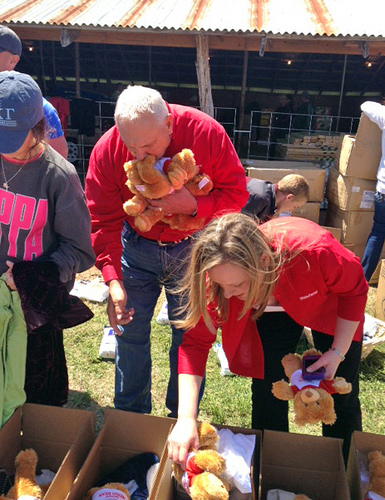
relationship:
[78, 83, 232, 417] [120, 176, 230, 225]
man holding teddy bear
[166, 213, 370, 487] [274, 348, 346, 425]
lady holding teddy bear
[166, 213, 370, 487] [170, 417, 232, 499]
lady holding bear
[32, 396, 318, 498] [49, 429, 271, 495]
boxes filled with teddy bears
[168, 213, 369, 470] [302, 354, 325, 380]
lady holding phone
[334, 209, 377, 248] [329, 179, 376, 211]
box stacked on box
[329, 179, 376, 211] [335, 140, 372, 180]
box stacked on box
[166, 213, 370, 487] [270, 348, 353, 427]
lady holding teddy bear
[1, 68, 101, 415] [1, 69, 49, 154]
woman wearing hat